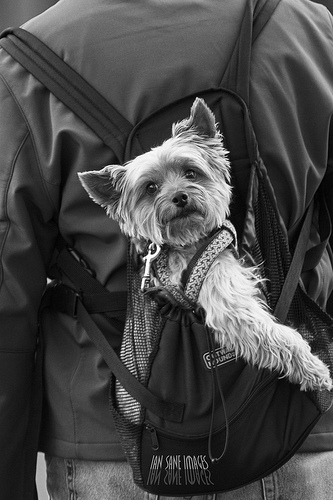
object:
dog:
[77, 98, 333, 399]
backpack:
[0, 3, 333, 500]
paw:
[295, 364, 332, 393]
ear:
[169, 98, 229, 141]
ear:
[76, 162, 121, 215]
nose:
[169, 193, 192, 210]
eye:
[183, 167, 200, 181]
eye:
[142, 180, 159, 199]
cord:
[206, 332, 231, 464]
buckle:
[59, 282, 79, 320]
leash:
[151, 223, 237, 309]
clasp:
[137, 240, 163, 292]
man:
[0, 0, 332, 499]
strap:
[2, 24, 138, 157]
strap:
[217, 1, 281, 105]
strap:
[275, 207, 318, 317]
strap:
[80, 310, 117, 386]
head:
[79, 96, 232, 251]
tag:
[156, 290, 200, 311]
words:
[145, 452, 164, 488]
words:
[204, 349, 238, 370]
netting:
[138, 350, 145, 361]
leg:
[206, 259, 332, 392]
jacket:
[0, 5, 332, 496]